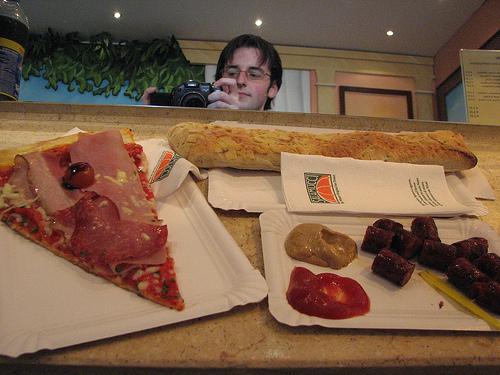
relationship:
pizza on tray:
[0, 133, 259, 370] [4, 134, 266, 368]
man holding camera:
[142, 33, 282, 112] [150, 85, 222, 106]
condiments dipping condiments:
[283, 219, 357, 270] [283, 219, 357, 270]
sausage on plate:
[417, 247, 484, 281] [255, 207, 498, 334]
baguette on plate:
[167, 120, 478, 173] [203, 119, 486, 219]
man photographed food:
[142, 33, 282, 112] [1, 122, 499, 331]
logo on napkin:
[302, 168, 341, 207] [277, 148, 486, 216]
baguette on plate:
[167, 120, 478, 173] [237, 207, 289, 252]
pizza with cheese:
[0, 127, 191, 310] [54, 217, 75, 233]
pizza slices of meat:
[0, 127, 191, 310] [67, 128, 145, 218]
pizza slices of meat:
[0, 127, 191, 310] [72, 219, 173, 260]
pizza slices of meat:
[0, 127, 191, 310] [10, 152, 73, 214]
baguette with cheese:
[167, 120, 478, 173] [212, 137, 235, 155]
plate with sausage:
[256, 195, 498, 337] [430, 245, 493, 295]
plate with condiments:
[256, 195, 498, 337] [285, 192, 363, 326]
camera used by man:
[151, 80, 217, 109] [208, 32, 283, 110]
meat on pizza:
[72, 219, 173, 260] [2, 117, 199, 310]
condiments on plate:
[283, 219, 357, 270] [256, 195, 498, 337]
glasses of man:
[144, 35, 284, 109] [224, 63, 270, 80]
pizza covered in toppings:
[0, 127, 191, 310] [20, 129, 172, 281]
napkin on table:
[276, 150, 460, 216] [2, 100, 497, 365]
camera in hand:
[145, 82, 225, 107] [136, 73, 241, 116]